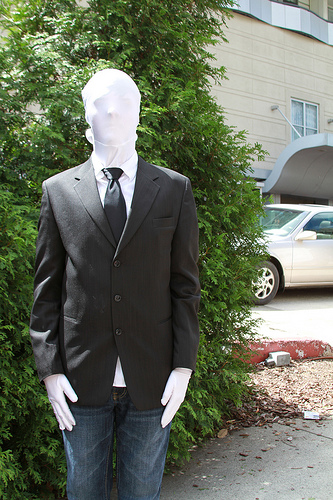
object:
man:
[30, 69, 201, 497]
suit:
[29, 162, 200, 408]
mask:
[82, 68, 141, 158]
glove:
[161, 363, 193, 427]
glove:
[43, 371, 79, 433]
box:
[265, 350, 291, 365]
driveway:
[230, 296, 333, 341]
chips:
[233, 358, 333, 413]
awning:
[263, 133, 333, 197]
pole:
[273, 101, 303, 138]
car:
[230, 203, 333, 308]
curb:
[224, 338, 333, 366]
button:
[115, 327, 123, 336]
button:
[114, 293, 123, 301]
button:
[112, 258, 119, 270]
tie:
[101, 166, 126, 247]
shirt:
[91, 148, 138, 219]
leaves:
[219, 386, 298, 432]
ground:
[0, 351, 333, 498]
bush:
[0, 0, 270, 498]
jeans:
[62, 391, 170, 499]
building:
[184, 0, 333, 207]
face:
[92, 90, 134, 145]